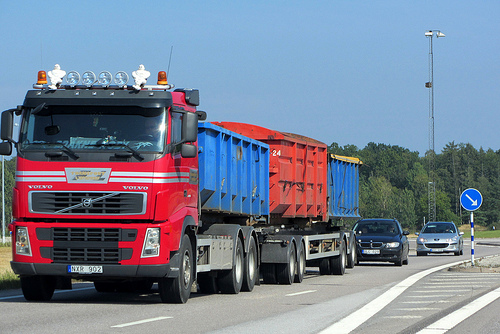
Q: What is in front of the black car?
A: A red and blue truck.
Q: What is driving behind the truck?
A: Two cars.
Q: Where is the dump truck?
A: On the road.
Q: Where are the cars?
A: Behind the dump truck.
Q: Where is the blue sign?
A: In the median.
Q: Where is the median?
A: Beneath the blue sign.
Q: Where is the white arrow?
A: On the blue sign.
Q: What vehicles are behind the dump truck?
A: Cars.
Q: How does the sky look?
A: Clear.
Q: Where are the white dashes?
A: Middle of road.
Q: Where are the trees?
A: In the distance.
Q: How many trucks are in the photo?
A: One.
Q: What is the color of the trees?
A: Green.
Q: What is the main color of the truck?
A: Red.